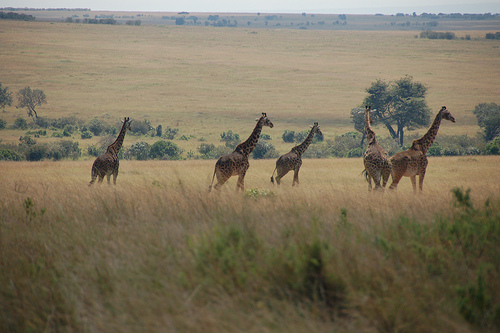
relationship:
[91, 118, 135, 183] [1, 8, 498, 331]
giraffe in plain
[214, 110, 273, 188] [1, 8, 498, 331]
giraffe in plain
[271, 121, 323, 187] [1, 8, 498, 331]
giraffe in plain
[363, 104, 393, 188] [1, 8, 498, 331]
giraffe in plain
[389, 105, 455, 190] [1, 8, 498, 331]
giraffe in plain